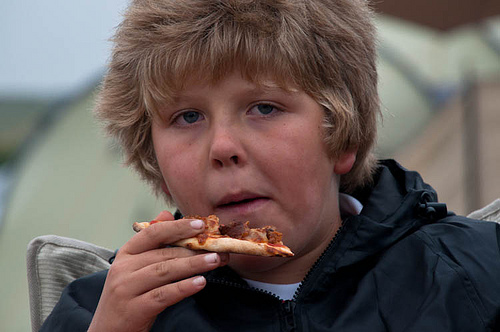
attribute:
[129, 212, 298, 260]
pizza — thin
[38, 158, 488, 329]
windbreaker — black, blue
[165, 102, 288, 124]
eyes — blue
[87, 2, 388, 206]
hair — blonde, feathered, short, blond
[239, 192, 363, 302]
shirt — white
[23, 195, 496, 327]
chair — gray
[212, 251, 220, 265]
fingernails — dirty